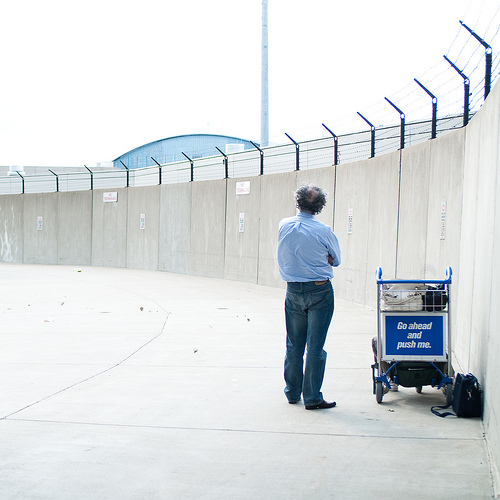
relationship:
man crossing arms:
[276, 187, 340, 409] [323, 229, 341, 269]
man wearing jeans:
[276, 187, 340, 409] [279, 283, 337, 404]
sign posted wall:
[102, 190, 118, 202] [7, 182, 209, 264]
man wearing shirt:
[276, 187, 340, 409] [249, 212, 360, 285]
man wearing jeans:
[276, 187, 340, 409] [282, 283, 333, 406]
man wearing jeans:
[276, 187, 340, 409] [279, 275, 339, 408]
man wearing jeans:
[269, 179, 344, 414] [272, 275, 339, 408]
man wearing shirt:
[269, 179, 344, 414] [273, 214, 341, 284]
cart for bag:
[371, 265, 456, 404] [431, 372, 483, 418]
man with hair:
[276, 187, 340, 409] [287, 181, 337, 216]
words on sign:
[393, 320, 435, 350] [381, 312, 453, 362]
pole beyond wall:
[260, 0, 269, 147] [1, 79, 498, 498]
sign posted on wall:
[229, 176, 253, 195] [1, 79, 498, 498]